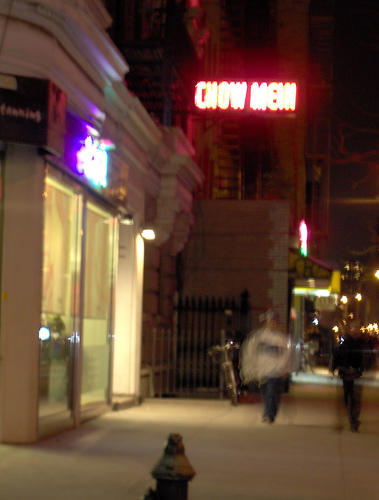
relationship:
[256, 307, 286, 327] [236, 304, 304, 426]
head on person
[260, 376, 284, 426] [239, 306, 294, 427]
leg on person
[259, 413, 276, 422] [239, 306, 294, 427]
feet on person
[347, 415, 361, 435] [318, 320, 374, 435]
feet of person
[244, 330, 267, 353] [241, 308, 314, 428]
arm on person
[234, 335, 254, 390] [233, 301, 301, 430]
arm on person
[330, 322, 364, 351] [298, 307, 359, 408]
head on person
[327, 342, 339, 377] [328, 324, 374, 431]
arm on person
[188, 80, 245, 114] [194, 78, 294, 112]
word on sign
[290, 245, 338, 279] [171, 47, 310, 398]
awning on building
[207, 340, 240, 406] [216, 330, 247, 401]
bicycle on sidewalk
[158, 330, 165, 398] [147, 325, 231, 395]
pole of fence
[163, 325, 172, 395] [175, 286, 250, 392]
pole of fence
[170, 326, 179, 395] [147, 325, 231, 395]
pole of fence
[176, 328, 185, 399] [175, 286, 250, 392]
pole of fence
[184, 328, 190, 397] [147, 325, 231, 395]
pole of fence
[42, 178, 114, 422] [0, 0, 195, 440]
window of business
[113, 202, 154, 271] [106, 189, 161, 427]
glowing light over over doorway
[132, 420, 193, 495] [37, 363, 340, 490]
fire hydrant on sidewalk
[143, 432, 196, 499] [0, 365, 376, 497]
fire hydrant on sidewalk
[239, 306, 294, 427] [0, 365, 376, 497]
person on sidewalk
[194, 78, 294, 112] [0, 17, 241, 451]
sign on side of building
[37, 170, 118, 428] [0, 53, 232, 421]
windows on building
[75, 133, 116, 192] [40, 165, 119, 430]
lighted sign over doorway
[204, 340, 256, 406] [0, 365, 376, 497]
bicycle parked on sidewalk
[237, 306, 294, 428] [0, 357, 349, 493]
person on sidewalk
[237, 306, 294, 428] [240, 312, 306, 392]
person in shirt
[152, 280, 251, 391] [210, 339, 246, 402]
iron fence beyond bicycle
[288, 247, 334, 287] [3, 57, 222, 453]
awning on side of building